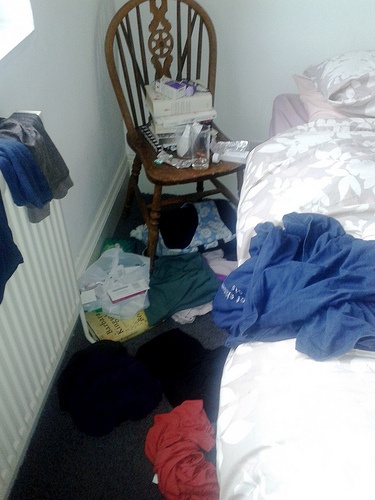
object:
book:
[144, 78, 213, 118]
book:
[151, 119, 214, 134]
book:
[140, 125, 212, 156]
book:
[149, 125, 213, 145]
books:
[160, 106, 217, 128]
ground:
[227, 118, 239, 142]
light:
[247, 360, 359, 457]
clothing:
[144, 251, 223, 328]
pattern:
[328, 60, 361, 91]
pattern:
[304, 150, 373, 207]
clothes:
[144, 398, 220, 500]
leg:
[146, 184, 162, 274]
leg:
[123, 154, 142, 210]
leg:
[237, 170, 244, 200]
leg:
[196, 182, 205, 202]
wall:
[0, 0, 374, 267]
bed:
[213, 92, 375, 500]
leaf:
[330, 147, 342, 160]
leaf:
[314, 148, 330, 160]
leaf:
[308, 158, 336, 169]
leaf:
[338, 174, 362, 201]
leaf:
[321, 192, 331, 207]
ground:
[248, 79, 288, 123]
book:
[85, 308, 166, 344]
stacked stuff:
[141, 77, 250, 170]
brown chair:
[103, 0, 246, 276]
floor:
[8, 188, 237, 500]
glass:
[190, 124, 211, 171]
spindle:
[175, 9, 198, 81]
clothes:
[211, 211, 375, 362]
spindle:
[196, 17, 203, 82]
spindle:
[186, 6, 192, 81]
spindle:
[176, 0, 182, 80]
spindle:
[115, 27, 139, 128]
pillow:
[302, 48, 374, 118]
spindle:
[135, 4, 149, 85]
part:
[62, 265, 79, 294]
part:
[17, 212, 38, 244]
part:
[9, 326, 65, 404]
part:
[2, 413, 24, 456]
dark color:
[67, 342, 206, 497]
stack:
[140, 75, 219, 154]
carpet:
[6, 196, 218, 499]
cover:
[144, 75, 217, 127]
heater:
[0, 110, 80, 500]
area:
[224, 12, 299, 82]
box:
[155, 75, 186, 101]